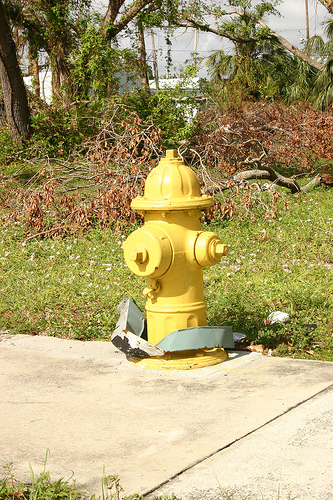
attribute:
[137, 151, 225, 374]
fire hydrant — yellow, here, sunlit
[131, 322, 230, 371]
base — round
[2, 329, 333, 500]
pavement — gray, concrete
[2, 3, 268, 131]
trees — grey, leaning, large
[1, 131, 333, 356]
grass — green, overgrown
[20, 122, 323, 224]
branch — broken, curved, down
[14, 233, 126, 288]
flowers — white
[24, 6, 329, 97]
leaves — orange